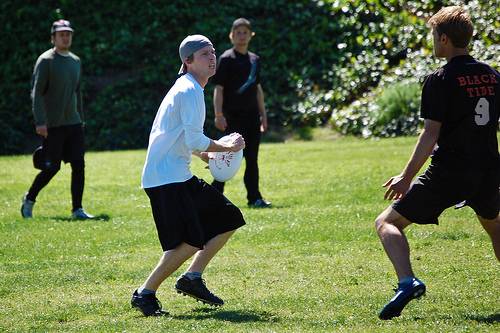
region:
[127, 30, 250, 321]
Young man is playing football.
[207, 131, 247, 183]
A white ball is in the man's hand.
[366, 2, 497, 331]
Opponent is guarding young man.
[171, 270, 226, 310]
A black sneaker is in the young man's foot.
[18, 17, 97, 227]
A guy wearing a green shirt.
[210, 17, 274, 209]
A spectator wearing a black shirt.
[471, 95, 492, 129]
Number nine is in the opponent's t-shirt.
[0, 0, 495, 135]
A ton of trees are in the background.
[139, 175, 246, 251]
One young man is wearing a black short.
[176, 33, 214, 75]
A grey hat in the young man's head.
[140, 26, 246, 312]
man holding white frisbee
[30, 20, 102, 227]
man wearing green long sleeved shirt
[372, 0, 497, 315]
man dressed in black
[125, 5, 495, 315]
a competitive game of ultimate frisbee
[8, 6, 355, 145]
rocks covered in vegetation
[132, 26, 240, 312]
man wearing white shirt and black shorts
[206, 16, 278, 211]
man wearing black shirt with blue stripe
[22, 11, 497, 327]
men playing a game in a park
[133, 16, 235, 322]
man about to toss a frisbee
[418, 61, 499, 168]
black shirt with red lettering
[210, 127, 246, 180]
the white rugby ball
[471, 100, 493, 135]
the white number 9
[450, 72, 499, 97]
the red lettering on the black tshirt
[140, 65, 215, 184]
the long white tshirt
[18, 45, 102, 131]
the long green tshirt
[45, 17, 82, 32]
the forward facing hat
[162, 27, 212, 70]
the backward facing hat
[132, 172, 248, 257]
the black shorts of the man holding the ball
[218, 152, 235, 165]
the red lettering on the rugby ball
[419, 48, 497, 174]
the black shirt with red lettering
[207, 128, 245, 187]
a white frisbee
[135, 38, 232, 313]
a young man holding a frisbee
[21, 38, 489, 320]
Four young men playing with a frisbee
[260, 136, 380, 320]
a large grassy field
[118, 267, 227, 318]
a pair of cleats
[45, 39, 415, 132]
a row of trees beside the field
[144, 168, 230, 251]
a pair of black shorts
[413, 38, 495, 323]
a man in black shorts and tee shirt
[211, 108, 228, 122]
an orange armband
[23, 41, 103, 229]
a man holding a ball cap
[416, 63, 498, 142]
black tee shirt with white number nine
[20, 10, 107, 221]
boy wearing green long sleeve shirt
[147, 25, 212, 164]
boy wearing white long sleeve shirt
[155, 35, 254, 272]
boy with frisbee in hands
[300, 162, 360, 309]
green grass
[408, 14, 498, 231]
backside of boy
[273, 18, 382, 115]
green leaves on trees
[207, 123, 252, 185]
white frisbee with red design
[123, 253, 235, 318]
black shoes and grey socks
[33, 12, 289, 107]
twins